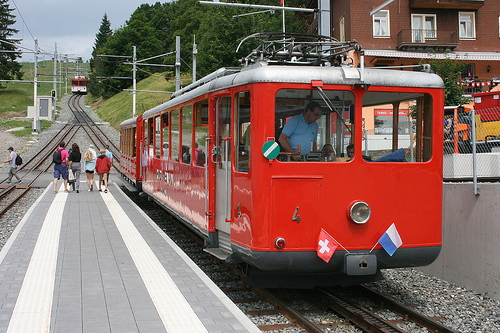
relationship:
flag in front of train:
[315, 225, 350, 262] [116, 62, 444, 291]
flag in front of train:
[370, 220, 404, 256] [116, 62, 444, 291]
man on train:
[276, 98, 321, 160] [116, 62, 444, 291]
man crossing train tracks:
[2, 148, 24, 183] [0, 93, 119, 240]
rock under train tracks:
[33, 188, 40, 191] [0, 93, 119, 240]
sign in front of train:
[260, 138, 281, 162] [116, 62, 444, 291]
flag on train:
[315, 225, 350, 262] [116, 62, 444, 291]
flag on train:
[370, 220, 404, 256] [116, 62, 444, 291]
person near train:
[95, 150, 110, 193] [116, 62, 444, 291]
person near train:
[83, 151, 98, 192] [116, 62, 444, 291]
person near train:
[68, 144, 83, 193] [116, 62, 444, 291]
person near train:
[54, 141, 70, 193] [116, 62, 444, 291]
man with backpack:
[2, 148, 24, 183] [15, 152, 22, 166]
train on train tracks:
[116, 62, 444, 291] [0, 93, 119, 240]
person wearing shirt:
[54, 141, 70, 193] [53, 146, 69, 162]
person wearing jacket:
[95, 150, 110, 193] [96, 155, 112, 173]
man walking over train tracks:
[2, 148, 24, 183] [0, 93, 119, 240]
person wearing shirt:
[68, 144, 83, 193] [68, 149, 81, 162]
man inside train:
[276, 98, 321, 160] [116, 62, 444, 291]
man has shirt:
[276, 98, 321, 160] [284, 113, 318, 152]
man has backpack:
[2, 148, 24, 183] [15, 152, 22, 166]